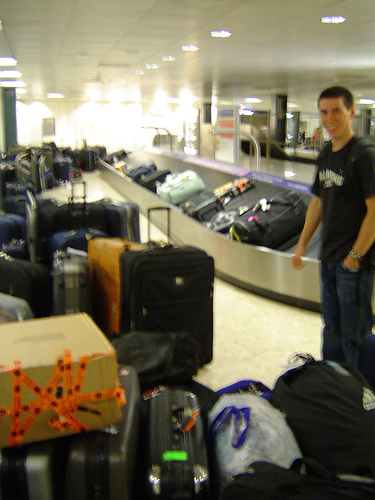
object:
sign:
[214, 105, 238, 163]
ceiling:
[0, 2, 375, 103]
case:
[269, 354, 375, 479]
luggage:
[207, 391, 306, 497]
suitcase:
[68, 365, 140, 500]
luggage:
[118, 206, 213, 369]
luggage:
[52, 247, 89, 318]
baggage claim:
[0, 140, 375, 500]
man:
[290, 86, 375, 389]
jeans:
[319, 254, 375, 370]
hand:
[289, 252, 307, 270]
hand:
[342, 253, 360, 272]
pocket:
[336, 261, 362, 291]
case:
[0, 251, 54, 319]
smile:
[320, 105, 348, 138]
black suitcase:
[145, 384, 210, 499]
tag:
[161, 449, 188, 462]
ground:
[39, 167, 325, 400]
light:
[0, 57, 17, 67]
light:
[0, 70, 23, 79]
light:
[0, 79, 25, 87]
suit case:
[54, 181, 106, 233]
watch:
[349, 249, 363, 263]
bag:
[111, 332, 199, 384]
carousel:
[100, 146, 322, 315]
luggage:
[229, 192, 307, 249]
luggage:
[180, 191, 224, 223]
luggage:
[155, 169, 204, 205]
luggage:
[140, 168, 172, 193]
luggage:
[127, 160, 157, 184]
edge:
[169, 333, 200, 378]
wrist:
[347, 249, 363, 261]